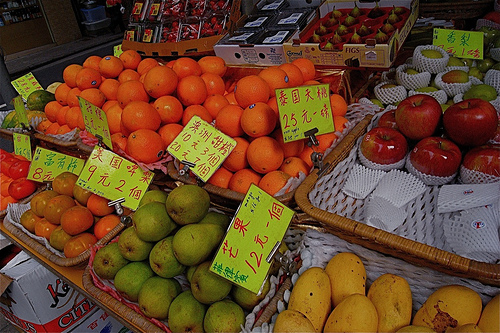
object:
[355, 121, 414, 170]
apple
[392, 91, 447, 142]
apple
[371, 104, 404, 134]
apple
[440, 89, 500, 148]
apple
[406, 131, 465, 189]
apple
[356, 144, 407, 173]
casing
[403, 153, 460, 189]
casing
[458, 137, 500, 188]
apple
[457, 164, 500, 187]
casing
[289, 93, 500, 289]
basket